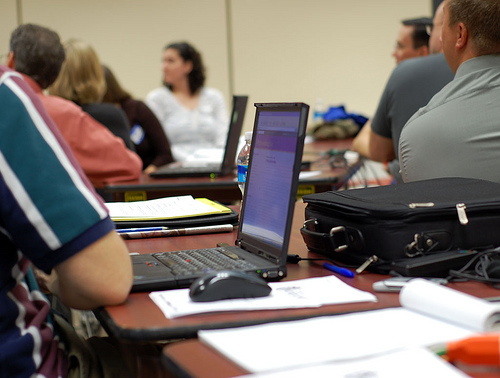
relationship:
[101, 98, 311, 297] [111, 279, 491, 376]
computer on a table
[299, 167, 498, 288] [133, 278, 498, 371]
bag on a table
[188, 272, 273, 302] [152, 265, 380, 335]
computer mouse on paper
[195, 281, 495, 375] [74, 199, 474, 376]
note pad on table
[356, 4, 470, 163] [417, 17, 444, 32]
man wearing glasses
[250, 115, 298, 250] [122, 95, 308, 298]
screen lit on laptop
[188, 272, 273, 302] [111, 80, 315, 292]
computer mouse near a laptop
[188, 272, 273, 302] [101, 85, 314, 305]
computer mouse near a laptop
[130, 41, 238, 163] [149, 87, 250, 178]
woman wearing shirt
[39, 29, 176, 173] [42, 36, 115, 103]
woman has hair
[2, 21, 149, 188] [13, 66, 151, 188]
man wearing shirt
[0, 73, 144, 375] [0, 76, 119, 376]
man wearing shirt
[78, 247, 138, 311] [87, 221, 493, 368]
elbow resting on table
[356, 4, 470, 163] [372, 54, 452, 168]
man wearing shirt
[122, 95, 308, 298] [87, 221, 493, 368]
laptop on table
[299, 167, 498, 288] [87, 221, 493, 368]
bag on table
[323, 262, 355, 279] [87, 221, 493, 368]
ink pen on table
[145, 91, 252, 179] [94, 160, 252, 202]
laptop on table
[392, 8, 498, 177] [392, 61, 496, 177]
person wearing shirt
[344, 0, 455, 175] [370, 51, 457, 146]
person wearing shirt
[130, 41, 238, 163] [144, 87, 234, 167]
woman wearing shirt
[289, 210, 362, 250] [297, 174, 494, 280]
handle on case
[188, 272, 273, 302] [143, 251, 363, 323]
computer mouse on papers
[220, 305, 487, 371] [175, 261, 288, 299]
paper by mouse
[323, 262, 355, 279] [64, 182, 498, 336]
ink pen on desk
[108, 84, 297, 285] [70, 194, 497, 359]
laptop on desk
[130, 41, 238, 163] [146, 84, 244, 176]
woman wearing a shirt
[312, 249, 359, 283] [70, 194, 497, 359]
ink pen on desk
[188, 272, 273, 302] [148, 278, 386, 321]
computer mouse on paper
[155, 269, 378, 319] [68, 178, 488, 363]
paper on desk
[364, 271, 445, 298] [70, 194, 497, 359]
cell phone on desk